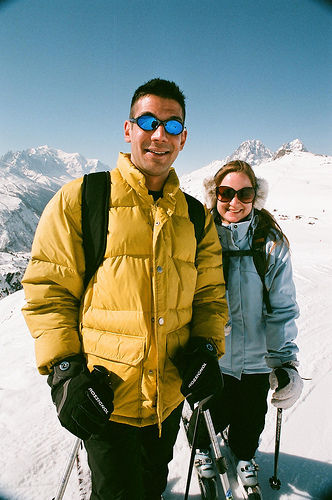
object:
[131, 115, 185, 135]
goggles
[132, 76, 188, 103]
hair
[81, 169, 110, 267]
backpack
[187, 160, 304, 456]
woman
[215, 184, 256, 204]
sunglasses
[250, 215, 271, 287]
backpack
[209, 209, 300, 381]
coat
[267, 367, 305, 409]
glove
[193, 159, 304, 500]
girl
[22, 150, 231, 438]
coat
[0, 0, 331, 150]
sky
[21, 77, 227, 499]
people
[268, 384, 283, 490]
ski poles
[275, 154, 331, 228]
snow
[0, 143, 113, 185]
mountain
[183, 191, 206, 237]
strap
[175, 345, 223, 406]
muff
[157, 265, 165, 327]
buttons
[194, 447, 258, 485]
boots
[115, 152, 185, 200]
collar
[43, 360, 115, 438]
glove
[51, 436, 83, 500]
pole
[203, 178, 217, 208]
ear muffs